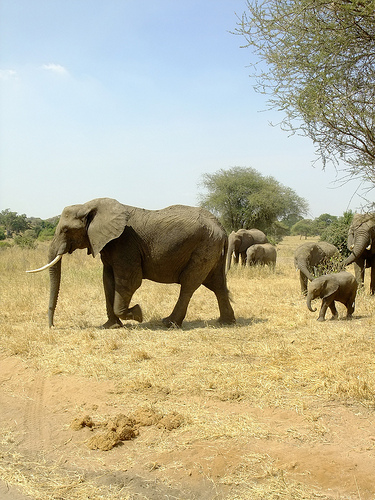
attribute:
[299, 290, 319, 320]
trunk — curled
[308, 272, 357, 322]
elephant — small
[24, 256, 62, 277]
white tusk — long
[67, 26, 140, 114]
sky — bad sentence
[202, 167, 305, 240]
bush — green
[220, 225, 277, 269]
elephant — small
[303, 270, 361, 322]
elephant — baby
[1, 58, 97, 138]
cloud — white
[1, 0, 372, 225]
sky — blue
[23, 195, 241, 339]
elephant — dark grey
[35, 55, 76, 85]
cloud — white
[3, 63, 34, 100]
cloud — white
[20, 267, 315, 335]
grass — yellow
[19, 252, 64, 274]
tusks — white